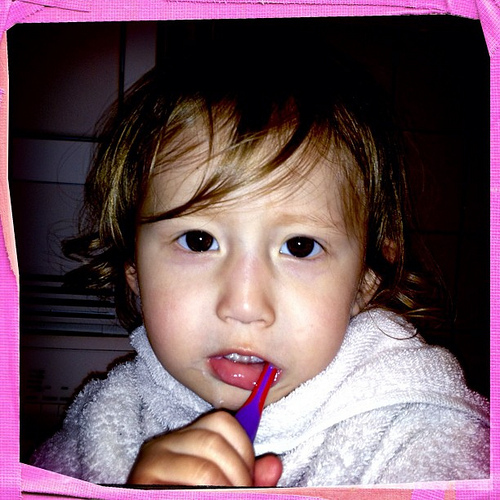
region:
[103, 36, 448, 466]
toddler with toothbrush in mouth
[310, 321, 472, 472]
terrycloth shirt on child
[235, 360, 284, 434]
red and purple toothbrush in mouth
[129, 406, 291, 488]
child's hand holding toothbrush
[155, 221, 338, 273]
brown eyes on child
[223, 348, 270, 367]
teeth in child's mouth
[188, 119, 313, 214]
bangs on child's forehead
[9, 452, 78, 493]
pink border around photo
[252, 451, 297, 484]
thumb on child's hand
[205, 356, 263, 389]
wet lower lip on child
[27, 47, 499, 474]
blond baby with blue toothbrush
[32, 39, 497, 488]
baby wearing white towel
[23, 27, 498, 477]
baby with curly hair and dark eyes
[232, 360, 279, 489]
blue and red toothbrush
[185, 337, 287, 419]
toothpaste around baby's mouth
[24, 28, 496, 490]
this is an indoor bathroom scene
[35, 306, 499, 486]
white fluffy terry cloth robe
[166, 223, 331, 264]
black almond eyes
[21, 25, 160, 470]
white walls in background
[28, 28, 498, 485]
white baby wearing white cloth holding blue toothbrush with blond curly hair and pink lips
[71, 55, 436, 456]
child brushing teeth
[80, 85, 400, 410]
long bangs swept to side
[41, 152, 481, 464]
child wearing terrycloth robe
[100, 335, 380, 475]
hand holding red and purple toothbrush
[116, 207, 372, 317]
child with very dark eyes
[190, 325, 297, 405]
lower lip pulled down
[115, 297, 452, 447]
child in robe up to chin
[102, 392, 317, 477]
thumb underneath fingers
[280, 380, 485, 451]
curve of robe hood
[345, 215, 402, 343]
ear covered by brown hair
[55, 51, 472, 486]
Little kid brushing their teeth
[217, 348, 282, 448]
Red and purple toothbrush handle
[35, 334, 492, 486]
White towel wrapped around the child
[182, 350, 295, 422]
Child's mouth with drool coming out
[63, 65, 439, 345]
Kid with curly, brown hair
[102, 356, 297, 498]
Child's hand holding a toothbrush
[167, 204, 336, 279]
Child's very dark brown eyes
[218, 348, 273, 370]
Child's white teeth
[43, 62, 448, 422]
Child staring at the camera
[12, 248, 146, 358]
Vent for the building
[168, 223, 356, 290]
kid's eyes are black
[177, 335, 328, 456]
the kid is holding a toothbrush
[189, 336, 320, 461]
the toothbrush is in the mouth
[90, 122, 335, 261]
the hair is brown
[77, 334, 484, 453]
the kid is wearing a towel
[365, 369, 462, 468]
the towel is white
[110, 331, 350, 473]
the kid is brushing his teeth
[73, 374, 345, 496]
the kid is holding the end of the toothbrush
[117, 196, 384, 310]
the kid has two eyes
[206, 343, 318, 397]
the kid has teeth